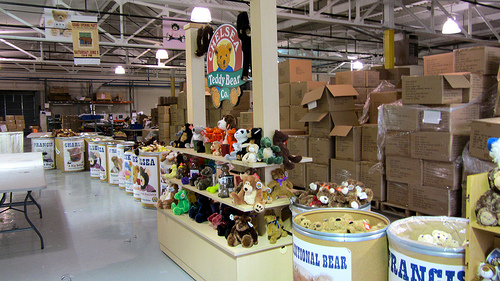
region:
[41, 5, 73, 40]
Banner with teddy bear wearing white shirt.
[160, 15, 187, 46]
Pink banner with teddy bear from ceiling.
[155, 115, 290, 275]
Display with three shelves of stuff animals.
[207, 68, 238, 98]
Teddy Bear Co. written in white.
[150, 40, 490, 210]
Rows of stacked boxes behind display.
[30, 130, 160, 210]
Line of barrels filled with stuffed animals below ceiling banners.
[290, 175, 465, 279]
Three barrels of stuffed animals between display cabinets.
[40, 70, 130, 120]
Metal rack of boxes against wall.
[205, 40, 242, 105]
Teddy bear in blue shirt in logo sign.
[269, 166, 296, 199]
Stuffed animal with purple ribbon.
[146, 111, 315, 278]
toys on the shelf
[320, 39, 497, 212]
stack of brown boxes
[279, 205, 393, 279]
a barrel full of toys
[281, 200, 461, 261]
two barrels full of toys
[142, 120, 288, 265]
three shelves with toys on them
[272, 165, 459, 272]
three barrels full of toys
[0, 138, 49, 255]
a metal table with a white cloth on it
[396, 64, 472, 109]
a opened cardboard box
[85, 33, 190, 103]
lights hanging from the cieling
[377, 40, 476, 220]
a stack of cardboard boxes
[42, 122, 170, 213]
several barrels in a row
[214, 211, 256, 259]
a brown teddy bear on a shelf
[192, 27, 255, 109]
Chelsea Teddy Bear Co. Sign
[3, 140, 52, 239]
An empty table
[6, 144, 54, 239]
This is a white folding table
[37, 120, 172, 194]
Many bins of teddy bears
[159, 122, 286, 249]
Three shelves of stuffed animals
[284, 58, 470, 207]
Stacks of boxes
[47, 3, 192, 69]
Signs hanging from the ceiling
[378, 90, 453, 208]
These boxes are wrapped in plastic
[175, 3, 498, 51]
Ceiling lights turned on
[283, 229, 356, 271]
Bin of traditional teddy bears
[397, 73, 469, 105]
Cardboard box stacked on others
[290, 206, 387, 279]
A barrel of stuffed animals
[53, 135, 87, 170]
A container of stuffed animals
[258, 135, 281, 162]
A green stuffed animal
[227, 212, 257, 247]
A brown bear stuffed animal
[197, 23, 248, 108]
A banner of a teddy bear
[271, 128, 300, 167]
A brown stuffed animal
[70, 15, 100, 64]
A brown and white banner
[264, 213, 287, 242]
A golden bear stuffed animal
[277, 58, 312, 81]
A brown cardboard box